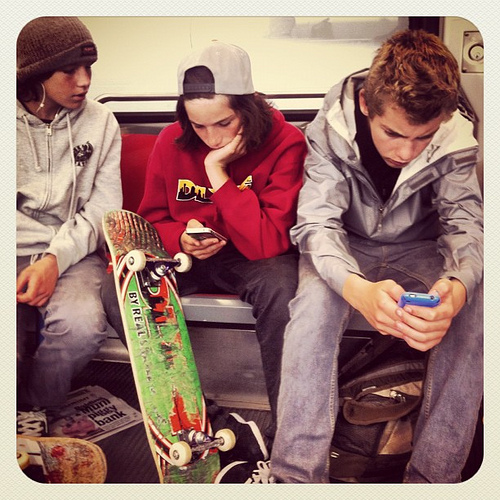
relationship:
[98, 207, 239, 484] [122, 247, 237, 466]
skateboard with wheels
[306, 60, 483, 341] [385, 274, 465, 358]
boy looking at phone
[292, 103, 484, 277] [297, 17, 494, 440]
jacket on boy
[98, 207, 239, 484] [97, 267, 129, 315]
skateboard against knee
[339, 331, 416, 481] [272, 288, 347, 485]
backpack behind legs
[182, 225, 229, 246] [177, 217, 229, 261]
smartphone in hand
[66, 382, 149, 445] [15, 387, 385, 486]
newspaper on floor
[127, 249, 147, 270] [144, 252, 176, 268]
wheel on truck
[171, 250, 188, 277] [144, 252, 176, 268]
wheel on truck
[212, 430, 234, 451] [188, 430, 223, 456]
wheel on truck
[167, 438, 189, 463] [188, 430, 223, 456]
wheel on truck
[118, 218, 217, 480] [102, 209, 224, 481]
underside of skateboard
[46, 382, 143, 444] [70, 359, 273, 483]
newspaper on floor